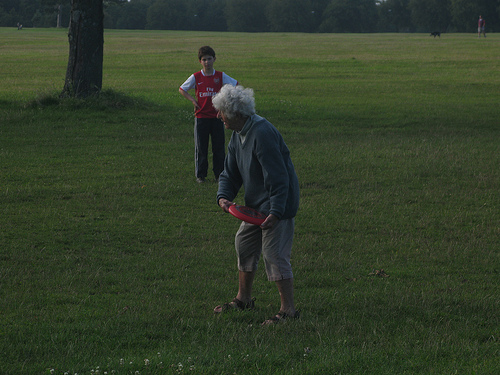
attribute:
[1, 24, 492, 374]
ground — green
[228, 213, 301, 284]
short — capri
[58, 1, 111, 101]
tree — large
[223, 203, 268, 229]
frisbee — small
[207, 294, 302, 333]
sandals — dark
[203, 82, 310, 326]
man — elderly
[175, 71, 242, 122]
jersey — red, white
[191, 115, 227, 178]
pants — black, white